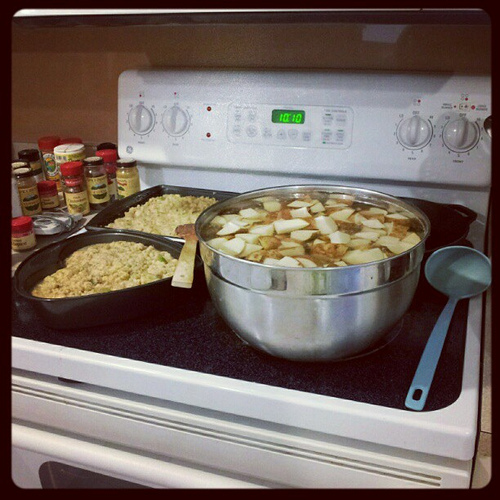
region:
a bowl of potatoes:
[229, 183, 418, 438]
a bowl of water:
[240, 168, 433, 365]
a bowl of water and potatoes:
[235, 152, 390, 405]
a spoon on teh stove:
[399, 209, 499, 394]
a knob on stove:
[442, 109, 469, 161]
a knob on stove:
[404, 101, 439, 155]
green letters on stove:
[269, 103, 314, 122]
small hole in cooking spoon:
[393, 382, 440, 407]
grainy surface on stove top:
[156, 326, 233, 357]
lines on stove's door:
[66, 390, 236, 448]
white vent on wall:
[349, 26, 419, 55]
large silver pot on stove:
[185, 180, 435, 333]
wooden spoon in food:
[160, 216, 212, 284]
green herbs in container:
[43, 158, 97, 217]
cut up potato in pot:
[247, 198, 344, 248]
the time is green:
[279, 112, 306, 119]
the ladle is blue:
[398, 247, 468, 416]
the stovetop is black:
[115, 297, 452, 403]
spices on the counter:
[15, 144, 138, 202]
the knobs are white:
[132, 103, 204, 147]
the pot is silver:
[214, 257, 399, 367]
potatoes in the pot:
[227, 197, 397, 270]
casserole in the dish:
[59, 247, 185, 293]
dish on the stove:
[30, 240, 193, 347]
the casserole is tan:
[135, 197, 210, 239]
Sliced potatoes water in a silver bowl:
[194, 180, 431, 366]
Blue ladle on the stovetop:
[405, 243, 495, 412]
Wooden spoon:
[173, 222, 200, 290]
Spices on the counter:
[11, 136, 145, 256]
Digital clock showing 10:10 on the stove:
[269, 108, 307, 124]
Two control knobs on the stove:
[126, 99, 198, 138]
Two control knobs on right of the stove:
[392, 112, 479, 154]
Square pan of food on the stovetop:
[83, 181, 240, 242]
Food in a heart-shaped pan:
[14, 225, 189, 323]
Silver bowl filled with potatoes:
[195, 182, 433, 364]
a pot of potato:
[223, 175, 412, 358]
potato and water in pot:
[214, 173, 339, 300]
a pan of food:
[54, 216, 143, 298]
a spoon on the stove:
[434, 223, 494, 423]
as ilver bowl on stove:
[199, 177, 428, 458]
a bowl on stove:
[190, 163, 497, 436]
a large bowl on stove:
[194, 165, 440, 385]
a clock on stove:
[266, 93, 317, 143]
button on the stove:
[298, 126, 321, 145]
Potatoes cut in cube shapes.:
[198, 149, 421, 299]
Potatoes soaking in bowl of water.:
[184, 160, 454, 378]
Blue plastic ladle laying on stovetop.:
[390, 166, 497, 435]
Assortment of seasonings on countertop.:
[4, 109, 151, 261]